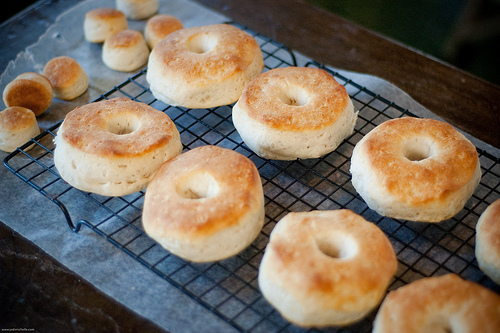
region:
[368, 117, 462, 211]
6 of 8 biscuits with center removed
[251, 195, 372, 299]
5th of 8 biscuit with center removed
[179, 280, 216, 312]
back cooling rack with biscuits on top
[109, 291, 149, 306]
white parchment paper under rack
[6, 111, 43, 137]
1 of 7 centers removed from biscuits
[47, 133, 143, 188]
1 of 8 biscuits with center removed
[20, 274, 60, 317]
black and gray area under rack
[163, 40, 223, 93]
2 of 8 biscuits with center removed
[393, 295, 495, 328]
1 of 7 biscuit with center removed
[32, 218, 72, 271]
wrinkle in parchment paper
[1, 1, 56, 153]
the bisquits on the wax paper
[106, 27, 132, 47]
the golden brown bisquit top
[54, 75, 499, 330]
the doughnuts on the rack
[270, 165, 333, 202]
the metal grate on the rack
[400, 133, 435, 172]
the hole in the doughnut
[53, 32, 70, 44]
a hole in the wax paper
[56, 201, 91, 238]
the leg stand for the oven rack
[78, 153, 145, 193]
the uneven dough with holes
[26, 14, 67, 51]
the trear in the wax paper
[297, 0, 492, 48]
tye wooden table umnder the baked goods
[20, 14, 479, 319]
donuts on a screen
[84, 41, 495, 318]
eight donuts in the picture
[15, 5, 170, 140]
seven donut holes on the side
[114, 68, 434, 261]
the donuts are golden brown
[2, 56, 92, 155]
the donut holes are golden brown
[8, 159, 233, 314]
the screen holding the donuts is black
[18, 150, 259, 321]
tissue paper is beneath the screen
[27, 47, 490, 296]
a wooden table is beneath the donuts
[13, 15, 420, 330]
these donuts are plain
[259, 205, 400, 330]
a doughnut on a cooling rack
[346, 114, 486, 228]
a doughnut on a cooling rack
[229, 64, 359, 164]
a doughnut on a cooling rack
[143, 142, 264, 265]
a doughnut on a cooling rack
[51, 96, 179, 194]
a doughnut on a cooling rack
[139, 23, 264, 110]
a doughnut on a cooling rack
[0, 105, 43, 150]
a doughnut hole on wax paper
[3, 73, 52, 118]
a doughnut hole on wax paper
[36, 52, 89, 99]
a doughnut hole on wax paper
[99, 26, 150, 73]
a doughnut hole on wax paper